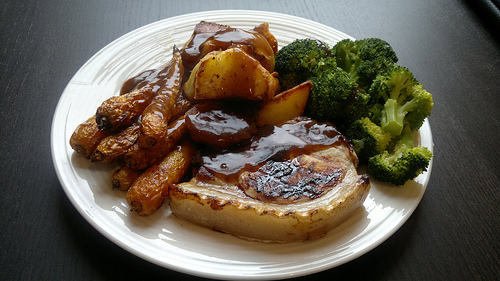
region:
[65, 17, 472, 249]
this is a plate of food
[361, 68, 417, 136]
this is a vegetable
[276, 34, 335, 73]
this is a vegetable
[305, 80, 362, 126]
this is a vegetable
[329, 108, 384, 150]
this is a vegetable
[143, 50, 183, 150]
this is a vegetable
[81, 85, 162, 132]
this is a vegetable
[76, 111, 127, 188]
this is a vegetable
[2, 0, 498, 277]
the table under the plate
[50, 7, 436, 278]
a white plate on the table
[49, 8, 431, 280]
a plate of food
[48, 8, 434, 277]
a dinner plate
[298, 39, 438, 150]
broccoli on the plate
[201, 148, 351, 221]
meat on the plate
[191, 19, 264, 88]
potatoes on the plate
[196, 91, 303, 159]
gravy on the food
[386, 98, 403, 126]
the stem of the broccoli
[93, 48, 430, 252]
a plate of food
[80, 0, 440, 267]
a plate of food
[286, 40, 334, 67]
broccoli on a plate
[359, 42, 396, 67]
broccoli on a plate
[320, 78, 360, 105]
broccoli on a plate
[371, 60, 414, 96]
broccoli on a plate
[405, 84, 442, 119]
broccoli on a plate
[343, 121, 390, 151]
broccoli on a plate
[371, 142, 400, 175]
broccoli on a plate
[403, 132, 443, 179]
broccoli on a plate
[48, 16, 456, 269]
plate on a table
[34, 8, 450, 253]
a table of broccoli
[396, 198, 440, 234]
par tof a line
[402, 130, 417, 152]
part f a vege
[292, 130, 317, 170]
par tof a line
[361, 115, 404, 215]
edge of a vege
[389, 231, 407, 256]
edge of a shade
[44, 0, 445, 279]
Food on a plate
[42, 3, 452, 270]
Food on a plate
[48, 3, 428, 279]
Food on a plate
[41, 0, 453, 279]
Food on a plate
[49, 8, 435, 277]
large round white plate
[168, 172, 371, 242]
large wide piece of bread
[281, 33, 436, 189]
large pile of broccoli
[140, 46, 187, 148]
long slick carrot cooked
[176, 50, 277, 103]
large sliced white potato